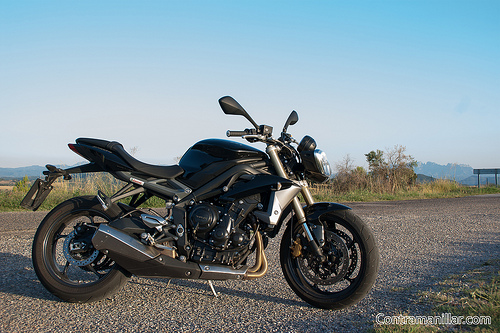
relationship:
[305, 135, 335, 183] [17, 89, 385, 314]
headlight on motorcycle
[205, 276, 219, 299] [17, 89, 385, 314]
kickstand on motorcycle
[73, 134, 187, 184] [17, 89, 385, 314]
seat on motorcycle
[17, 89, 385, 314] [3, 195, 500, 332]
motorcycle on road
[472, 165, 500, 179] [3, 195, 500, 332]
sign by road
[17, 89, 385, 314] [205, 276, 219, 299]
motorcycle on kickstand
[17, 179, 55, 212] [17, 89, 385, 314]
plate mounted motorcycle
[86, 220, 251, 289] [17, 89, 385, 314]
muffler on motorcycle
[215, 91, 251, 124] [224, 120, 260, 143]
mirrors on handlebars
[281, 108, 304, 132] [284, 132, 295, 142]
mirrors on handlebars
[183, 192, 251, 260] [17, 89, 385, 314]
engine on motorcycle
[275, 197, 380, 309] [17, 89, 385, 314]
tires on motorcycle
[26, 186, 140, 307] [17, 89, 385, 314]
tires on motorcycle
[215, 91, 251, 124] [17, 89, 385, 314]
mirrors on motorcycle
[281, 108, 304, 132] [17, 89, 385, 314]
mirrors on motorcycle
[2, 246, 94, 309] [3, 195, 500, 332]
shadow on road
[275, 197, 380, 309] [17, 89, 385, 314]
tires of motorcycle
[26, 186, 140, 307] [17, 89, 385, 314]
tires of motorcycle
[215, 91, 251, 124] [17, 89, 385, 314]
mirrors of motorcycle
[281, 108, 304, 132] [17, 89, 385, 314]
mirrors of motorcycle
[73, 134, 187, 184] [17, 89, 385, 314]
seat of motorcycle